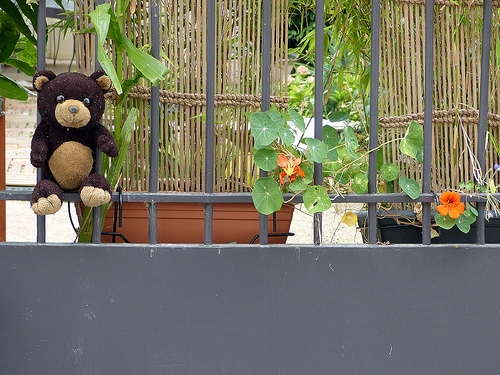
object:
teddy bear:
[23, 66, 125, 218]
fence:
[0, 0, 499, 243]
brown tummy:
[43, 137, 101, 194]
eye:
[54, 93, 67, 105]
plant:
[248, 107, 480, 236]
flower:
[433, 185, 473, 224]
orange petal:
[439, 191, 452, 204]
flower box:
[375, 204, 498, 246]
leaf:
[0, 75, 29, 104]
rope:
[107, 79, 303, 116]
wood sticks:
[73, 0, 293, 192]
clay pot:
[76, 198, 344, 245]